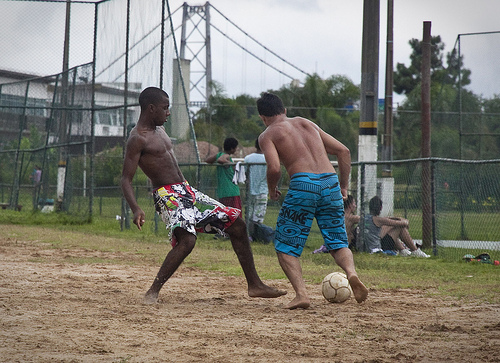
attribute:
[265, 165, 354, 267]
short — blue, colorful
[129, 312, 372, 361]
ground — brown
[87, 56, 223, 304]
man — shirtless, black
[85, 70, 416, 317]
boys — standing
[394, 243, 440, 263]
shoes — white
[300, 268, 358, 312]
ball — white, soccer, dirty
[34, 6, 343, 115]
bridge — grey, top, tall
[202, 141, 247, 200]
t-shirt — green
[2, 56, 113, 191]
fence — green, black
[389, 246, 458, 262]
sneakers — white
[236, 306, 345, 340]
dirt — muddy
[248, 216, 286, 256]
backpack — blue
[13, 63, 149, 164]
building — brown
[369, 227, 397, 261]
trunks — black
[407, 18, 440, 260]
pole — metal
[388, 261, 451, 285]
grass — green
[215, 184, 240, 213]
shorts — red